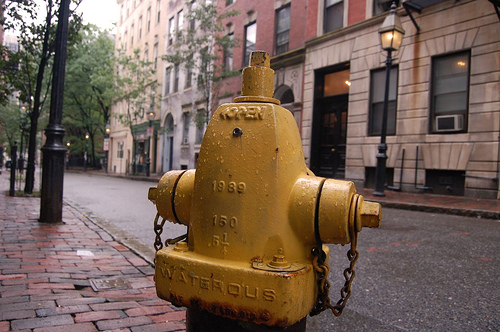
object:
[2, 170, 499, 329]
pavement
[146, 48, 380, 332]
fire hydrant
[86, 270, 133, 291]
cover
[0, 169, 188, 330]
sidewalk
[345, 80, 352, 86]
light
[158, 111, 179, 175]
doorway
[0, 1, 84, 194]
tree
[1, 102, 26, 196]
tree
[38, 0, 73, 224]
pole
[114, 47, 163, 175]
tree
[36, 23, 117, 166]
tree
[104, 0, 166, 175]
building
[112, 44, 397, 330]
fire hydrant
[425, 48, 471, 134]
window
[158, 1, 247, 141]
trees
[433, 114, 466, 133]
air conditioner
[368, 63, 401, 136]
window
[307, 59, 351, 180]
door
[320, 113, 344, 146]
glass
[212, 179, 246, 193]
raised numbers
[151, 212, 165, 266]
chains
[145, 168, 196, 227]
caps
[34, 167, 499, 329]
street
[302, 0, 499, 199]
building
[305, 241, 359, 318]
chain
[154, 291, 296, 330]
rust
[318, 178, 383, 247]
cap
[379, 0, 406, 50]
light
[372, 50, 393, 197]
light pole